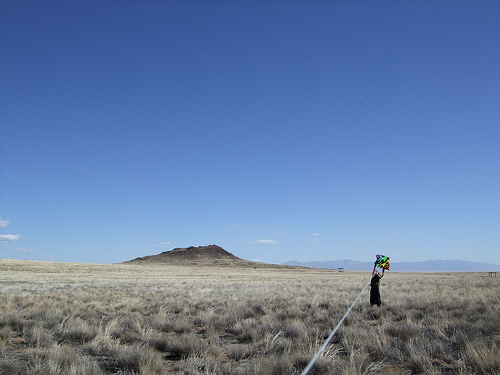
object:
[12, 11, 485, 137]
sky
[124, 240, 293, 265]
mountain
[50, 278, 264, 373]
field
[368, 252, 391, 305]
person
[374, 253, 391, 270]
kite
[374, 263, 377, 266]
hands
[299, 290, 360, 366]
string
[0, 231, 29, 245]
clouds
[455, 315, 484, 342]
grass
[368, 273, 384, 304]
outfit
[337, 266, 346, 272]
vehicle